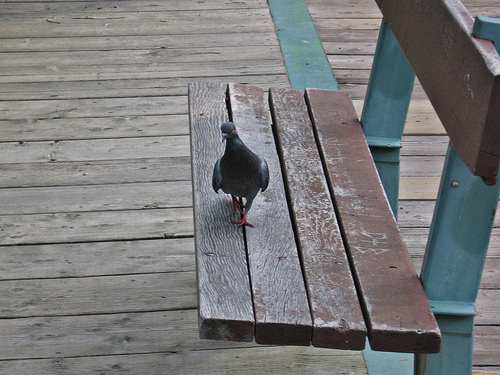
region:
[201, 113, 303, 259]
the bird is grey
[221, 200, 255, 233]
the feetare red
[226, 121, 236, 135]
the eyes are red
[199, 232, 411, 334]
the bench is brown and grey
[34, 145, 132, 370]
the floor is made of wood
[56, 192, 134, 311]
the wood is grey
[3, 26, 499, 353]
the photo was taken during the day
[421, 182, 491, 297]
the metal is blue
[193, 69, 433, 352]
the bench is made of four planks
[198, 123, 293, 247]
the dove is looking at the camera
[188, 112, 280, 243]
small pigeon sitting on bench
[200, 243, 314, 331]
two posts of a wooden bench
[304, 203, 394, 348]
dark brown back to bench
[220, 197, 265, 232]
orange feet of bench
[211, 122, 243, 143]
small blue head of pigeon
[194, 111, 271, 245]
pigeon walking forward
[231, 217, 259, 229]
talons on end of feet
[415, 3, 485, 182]
dark brown back board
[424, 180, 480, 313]
light blue support boards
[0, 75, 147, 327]
brown wooden deck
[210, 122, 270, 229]
A bird on a bench.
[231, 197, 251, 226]
The bird's feet.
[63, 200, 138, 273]
Part of the ground.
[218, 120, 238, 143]
The head of the bird.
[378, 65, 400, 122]
Part of the metal on the bench.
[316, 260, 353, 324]
part of the wood on the bench.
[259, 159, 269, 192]
The bird's right wing.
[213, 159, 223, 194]
The bird's left wing.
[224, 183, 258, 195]
The bird's gray chest.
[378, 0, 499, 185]
The top board on the bench.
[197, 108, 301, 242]
the bird is on a bench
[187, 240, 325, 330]
the bench is made of wood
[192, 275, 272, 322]
the bench is brown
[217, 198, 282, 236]
the bird has red feet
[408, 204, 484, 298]
the pole is blue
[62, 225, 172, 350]
the ground is made of wood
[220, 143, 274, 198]
the bird has black feathers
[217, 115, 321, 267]
the bird is walking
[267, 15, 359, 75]
green metal is on the ground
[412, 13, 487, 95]
brown backing is on the bench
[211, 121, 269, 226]
grey bird on bench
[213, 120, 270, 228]
pigeon standing on bench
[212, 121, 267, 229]
grey bird with orange legs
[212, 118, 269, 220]
grey bird with grey beak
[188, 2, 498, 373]
blue and brown bench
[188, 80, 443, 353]
brown wood bench seat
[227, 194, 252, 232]
orange legs on bird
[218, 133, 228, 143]
grey beak on bird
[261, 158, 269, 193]
grey wing on bird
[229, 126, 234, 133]
orange eye on bird